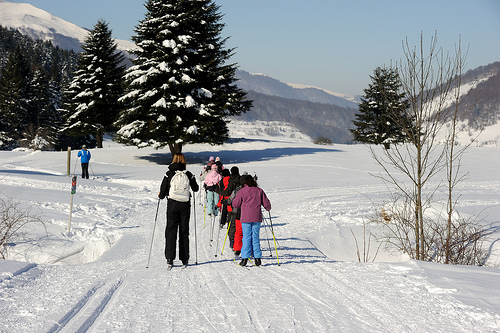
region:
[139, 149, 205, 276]
The woman in black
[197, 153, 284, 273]
The line of young skiers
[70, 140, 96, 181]
The lone man in the blue jacket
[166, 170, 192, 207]
The woman's white backpack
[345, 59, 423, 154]
The lone pine tree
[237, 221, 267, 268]
The blue pants of the last child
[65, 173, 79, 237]
The green and red sign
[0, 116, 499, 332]
The snow covered ground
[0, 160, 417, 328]
The trail the skiers are following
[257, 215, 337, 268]
The shadows of the young skiers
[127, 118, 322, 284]
GROUP OF SNOW SKIERS ON SLOPE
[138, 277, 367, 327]
SKI TRACKS IN WHITE SNOW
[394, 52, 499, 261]
LEAVE-LESS BUSHES ON RIGHT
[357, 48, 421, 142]
WHITE SNOW ON GREEN TREE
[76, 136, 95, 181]
BLUE SPECTATOR IN THE DISTANCE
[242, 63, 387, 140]
TREE COVERED MOUNTAINS IN THE DISTANCE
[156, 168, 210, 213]
WHITE BACKPACK ON SKIER IN BLACK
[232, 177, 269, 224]
PURPLE SNOW JACKET ON SKIER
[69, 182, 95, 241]
SMALL SIGN STICKING OUT OF SNOW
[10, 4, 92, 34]
SNOW COVERED PEAK ON LEFT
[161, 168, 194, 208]
woman wearing backpack on back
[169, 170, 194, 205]
woman's backpack is white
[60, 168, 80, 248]
colorful pole in snow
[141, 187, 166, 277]
woman is holding ski pole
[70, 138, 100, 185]
man is standing in the snow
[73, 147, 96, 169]
man is wearing blue jacket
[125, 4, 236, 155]
snow is scattered on tree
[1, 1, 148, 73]
mountain is snow capped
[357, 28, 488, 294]
bare tree in the snow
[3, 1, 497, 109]
sky is gray and overcast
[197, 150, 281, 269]
A line of people skiing.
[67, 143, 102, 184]
A skier wearing a blue coat.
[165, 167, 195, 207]
A white backpack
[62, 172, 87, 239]
A sign on a pole in the snow.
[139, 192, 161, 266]
A black ski pole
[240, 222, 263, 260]
A blue pair of ski pants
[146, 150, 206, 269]
A woman skiing.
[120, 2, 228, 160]
A large tree covered with snow.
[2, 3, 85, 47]
A snow covered mountain peak.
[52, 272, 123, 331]
A set of ski tracks.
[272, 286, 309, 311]
the snow is visible and white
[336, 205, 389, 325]
the snow is visible and white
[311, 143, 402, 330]
the snow is visible and white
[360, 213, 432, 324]
the snow is visible and white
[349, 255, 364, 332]
the snow is visible and white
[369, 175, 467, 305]
the snow is visible and white